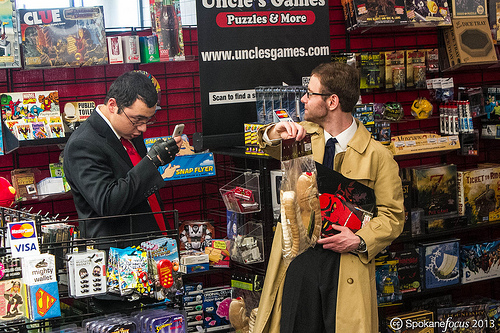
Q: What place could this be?
A: It is a store.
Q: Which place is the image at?
A: It is at the store.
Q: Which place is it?
A: It is a store.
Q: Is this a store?
A: Yes, it is a store.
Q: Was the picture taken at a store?
A: Yes, it was taken in a store.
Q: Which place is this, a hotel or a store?
A: It is a store.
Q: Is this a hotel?
A: No, it is a store.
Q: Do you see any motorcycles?
A: No, there are no motorcycles.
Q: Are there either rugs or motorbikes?
A: No, there are no motorbikes or rugs.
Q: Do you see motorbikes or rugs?
A: No, there are no motorbikes or rugs.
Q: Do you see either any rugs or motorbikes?
A: No, there are no motorbikes or rugs.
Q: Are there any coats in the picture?
A: Yes, there is a coat.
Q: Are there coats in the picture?
A: Yes, there is a coat.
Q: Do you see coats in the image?
A: Yes, there is a coat.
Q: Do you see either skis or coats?
A: Yes, there is a coat.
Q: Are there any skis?
A: No, there are no skis.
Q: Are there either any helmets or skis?
A: No, there are no skis or helmets.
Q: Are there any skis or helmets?
A: No, there are no skis or helmets.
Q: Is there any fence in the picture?
A: No, there are no fences.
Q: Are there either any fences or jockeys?
A: No, there are no fences or jockeys.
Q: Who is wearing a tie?
A: The man is wearing a tie.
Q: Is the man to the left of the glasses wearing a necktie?
A: Yes, the man is wearing a necktie.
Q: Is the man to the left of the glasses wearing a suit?
A: No, the man is wearing a necktie.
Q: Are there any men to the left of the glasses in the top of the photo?
A: Yes, there is a man to the left of the glasses.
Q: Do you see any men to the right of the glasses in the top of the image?
A: No, the man is to the left of the glasses.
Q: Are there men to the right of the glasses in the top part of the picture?
A: No, the man is to the left of the glasses.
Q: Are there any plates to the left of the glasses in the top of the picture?
A: No, there is a man to the left of the glasses.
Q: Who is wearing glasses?
A: The man is wearing glasses.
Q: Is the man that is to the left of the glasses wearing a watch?
A: Yes, the man is wearing a watch.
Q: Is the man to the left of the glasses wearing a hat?
A: No, the man is wearing a watch.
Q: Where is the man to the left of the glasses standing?
A: The man is standing in the store.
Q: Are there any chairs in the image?
A: No, there are no chairs.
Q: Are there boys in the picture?
A: No, there are no boys.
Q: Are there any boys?
A: No, there are no boys.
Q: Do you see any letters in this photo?
A: Yes, there are letters.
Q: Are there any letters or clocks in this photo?
A: Yes, there are letters.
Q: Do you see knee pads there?
A: No, there are no knee pads.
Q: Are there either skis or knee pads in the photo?
A: No, there are no knee pads or skis.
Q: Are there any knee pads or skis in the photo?
A: No, there are no knee pads or skis.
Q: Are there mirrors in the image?
A: No, there are no mirrors.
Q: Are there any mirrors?
A: No, there are no mirrors.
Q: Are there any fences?
A: No, there are no fences.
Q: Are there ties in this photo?
A: Yes, there is a tie.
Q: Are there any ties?
A: Yes, there is a tie.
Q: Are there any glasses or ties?
A: Yes, there is a tie.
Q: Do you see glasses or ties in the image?
A: Yes, there is a tie.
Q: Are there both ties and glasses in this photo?
A: Yes, there are both a tie and glasses.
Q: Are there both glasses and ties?
A: Yes, there are both a tie and glasses.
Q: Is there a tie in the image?
A: Yes, there is a tie.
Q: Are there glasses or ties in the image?
A: Yes, there is a tie.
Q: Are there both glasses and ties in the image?
A: Yes, there are both a tie and glasses.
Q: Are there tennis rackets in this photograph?
A: No, there are no tennis rackets.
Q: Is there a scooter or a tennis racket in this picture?
A: No, there are no rackets or scooters.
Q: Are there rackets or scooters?
A: No, there are no rackets or scooters.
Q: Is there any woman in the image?
A: No, there are no women.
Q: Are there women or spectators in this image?
A: No, there are no women or spectators.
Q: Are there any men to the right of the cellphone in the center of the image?
A: Yes, there is a man to the right of the cellphone.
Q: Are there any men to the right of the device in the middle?
A: Yes, there is a man to the right of the cellphone.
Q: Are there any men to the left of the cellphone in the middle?
A: No, the man is to the right of the mobile phone.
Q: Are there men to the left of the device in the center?
A: No, the man is to the right of the mobile phone.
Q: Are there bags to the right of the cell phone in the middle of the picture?
A: No, there is a man to the right of the mobile phone.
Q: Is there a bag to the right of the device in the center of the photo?
A: No, there is a man to the right of the mobile phone.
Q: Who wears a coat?
A: The man wears a coat.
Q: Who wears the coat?
A: The man wears a coat.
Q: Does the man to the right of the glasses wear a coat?
A: Yes, the man wears a coat.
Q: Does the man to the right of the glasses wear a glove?
A: No, the man wears a coat.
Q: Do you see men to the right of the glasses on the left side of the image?
A: Yes, there is a man to the right of the glasses.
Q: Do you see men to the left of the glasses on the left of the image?
A: No, the man is to the right of the glasses.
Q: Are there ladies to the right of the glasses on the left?
A: No, there is a man to the right of the glasses.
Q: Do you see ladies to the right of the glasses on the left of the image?
A: No, there is a man to the right of the glasses.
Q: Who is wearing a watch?
A: The man is wearing a watch.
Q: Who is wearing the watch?
A: The man is wearing a watch.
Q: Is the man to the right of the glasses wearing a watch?
A: Yes, the man is wearing a watch.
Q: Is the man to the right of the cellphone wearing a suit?
A: No, the man is wearing a watch.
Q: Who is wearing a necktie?
A: The man is wearing a necktie.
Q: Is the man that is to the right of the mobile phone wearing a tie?
A: Yes, the man is wearing a tie.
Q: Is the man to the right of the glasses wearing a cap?
A: No, the man is wearing a tie.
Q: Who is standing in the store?
A: The man is standing in the store.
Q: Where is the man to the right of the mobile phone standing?
A: The man is standing in the store.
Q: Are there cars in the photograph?
A: No, there are no cars.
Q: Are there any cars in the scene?
A: No, there are no cars.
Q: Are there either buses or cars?
A: No, there are no cars or buses.